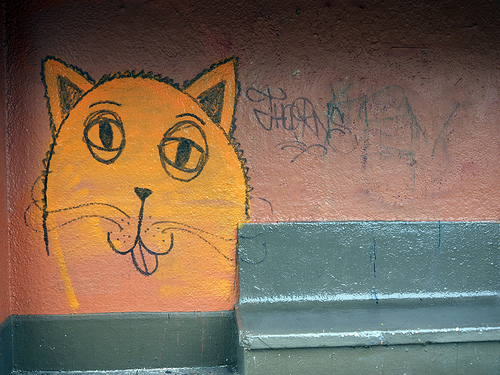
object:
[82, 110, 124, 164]
eye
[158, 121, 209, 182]
eye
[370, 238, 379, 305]
streak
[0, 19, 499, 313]
wall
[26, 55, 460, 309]
graffiti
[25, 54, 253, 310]
cat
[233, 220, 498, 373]
bench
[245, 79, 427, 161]
bracelet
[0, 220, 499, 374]
green paint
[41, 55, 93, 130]
ear